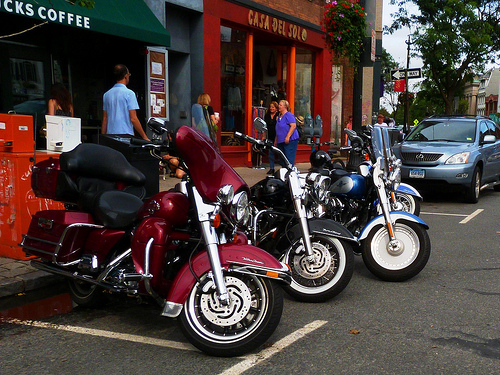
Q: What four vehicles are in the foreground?
A: Motorcycles.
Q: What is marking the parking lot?
A: White stripes.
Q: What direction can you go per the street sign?
A: One way.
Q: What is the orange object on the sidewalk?
A: Newspaper dispenser.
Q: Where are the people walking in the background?
A: Sidewalk.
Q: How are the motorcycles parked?
A: Side by side.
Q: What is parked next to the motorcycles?
A: A car.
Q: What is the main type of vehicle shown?
A: Motorcycle.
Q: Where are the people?
A: Outside a restaurant.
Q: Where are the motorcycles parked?
A: In the street.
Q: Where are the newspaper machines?
A: On the sidewalk.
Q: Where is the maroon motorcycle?
A: Parked in the street.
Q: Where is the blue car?
A: Parked in the street.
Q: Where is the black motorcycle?
A: Parked in the street.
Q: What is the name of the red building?
A: Casa Del Sol.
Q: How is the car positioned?
A: In park.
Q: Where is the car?
A: Road.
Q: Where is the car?
A: Road.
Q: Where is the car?
A: Road.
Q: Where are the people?
A: Side.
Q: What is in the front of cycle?
A: Wheel.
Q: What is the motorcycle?
A: Burgundy.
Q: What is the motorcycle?
A: Blue.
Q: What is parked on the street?
A: The car.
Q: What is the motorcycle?
A: Parked.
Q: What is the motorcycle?
A: Parked.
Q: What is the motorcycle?
A: Parked.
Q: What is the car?
A: Blue.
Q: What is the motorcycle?
A: Cranberry.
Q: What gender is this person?
A: Male.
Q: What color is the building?
A: Red.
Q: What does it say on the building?
A: Case Del Solo.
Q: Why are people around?
A: They are walking to and from places.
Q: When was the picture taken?
A: In the daytime.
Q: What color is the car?
A: Blue.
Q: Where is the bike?
A: On the street.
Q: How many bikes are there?
A: Four.